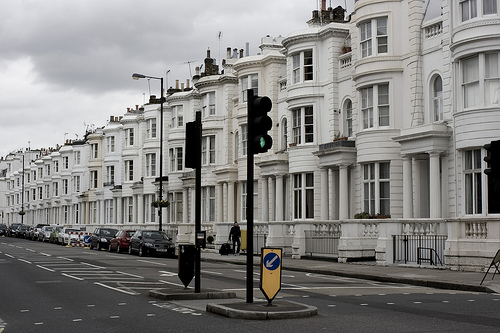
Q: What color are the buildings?
A: White.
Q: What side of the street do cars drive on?
A: The left.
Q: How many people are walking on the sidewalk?
A: One.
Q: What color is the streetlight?
A: Green.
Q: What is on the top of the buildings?
A: Chimneys.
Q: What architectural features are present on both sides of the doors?
A: Columns.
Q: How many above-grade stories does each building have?
A: Three.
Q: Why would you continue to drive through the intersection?
A: The light is green.